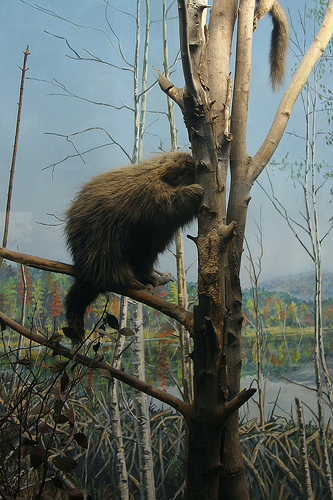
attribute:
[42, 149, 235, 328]
beaver — brown 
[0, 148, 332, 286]
clouds — white 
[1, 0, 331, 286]
sky — blue 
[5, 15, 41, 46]
cloud — white  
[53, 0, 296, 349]
animals — taxidermied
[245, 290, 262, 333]
tree — green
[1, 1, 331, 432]
sky — blue 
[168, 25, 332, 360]
tree — top 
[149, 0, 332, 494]
tree — tan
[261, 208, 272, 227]
sky — blue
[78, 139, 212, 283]
brown beaver — brown 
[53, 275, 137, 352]
tail — bushy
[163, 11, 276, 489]
trunks — tall, brown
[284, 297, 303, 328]
tree — green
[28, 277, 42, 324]
tree — green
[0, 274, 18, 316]
tree — green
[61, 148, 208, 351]
beaver — furry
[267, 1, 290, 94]
tail — bushy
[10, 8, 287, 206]
clouds — white  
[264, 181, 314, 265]
clouds — white  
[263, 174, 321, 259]
clouds — white 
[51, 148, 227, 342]
animal — tail 